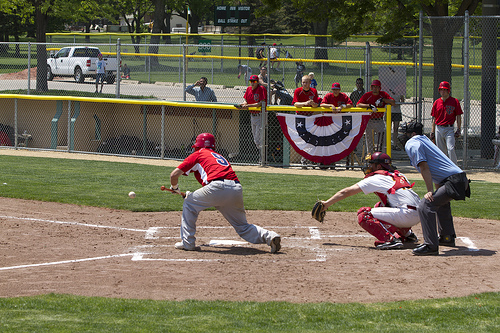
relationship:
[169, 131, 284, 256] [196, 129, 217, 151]
batter has helmet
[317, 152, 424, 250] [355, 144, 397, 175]
catcher has red helmet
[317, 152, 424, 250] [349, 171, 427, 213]
catcher has shirt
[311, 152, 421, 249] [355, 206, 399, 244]
catcher has red shinguards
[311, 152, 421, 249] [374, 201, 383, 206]
catcher has red shinguards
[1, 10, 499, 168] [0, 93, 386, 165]
fence near dugout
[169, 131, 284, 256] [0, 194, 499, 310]
batter standing in dirt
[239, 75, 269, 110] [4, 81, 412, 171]
player standing near dugout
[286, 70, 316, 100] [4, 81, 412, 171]
player standing near dugout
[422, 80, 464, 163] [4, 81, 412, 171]
player standing near dugout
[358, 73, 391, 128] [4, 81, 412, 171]
player standing near dugout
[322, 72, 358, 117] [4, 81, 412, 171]
player standing near dugout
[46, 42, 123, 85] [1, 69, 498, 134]
truck on road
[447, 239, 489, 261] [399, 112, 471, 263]
shadow from umpire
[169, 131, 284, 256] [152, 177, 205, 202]
batter swinging bat